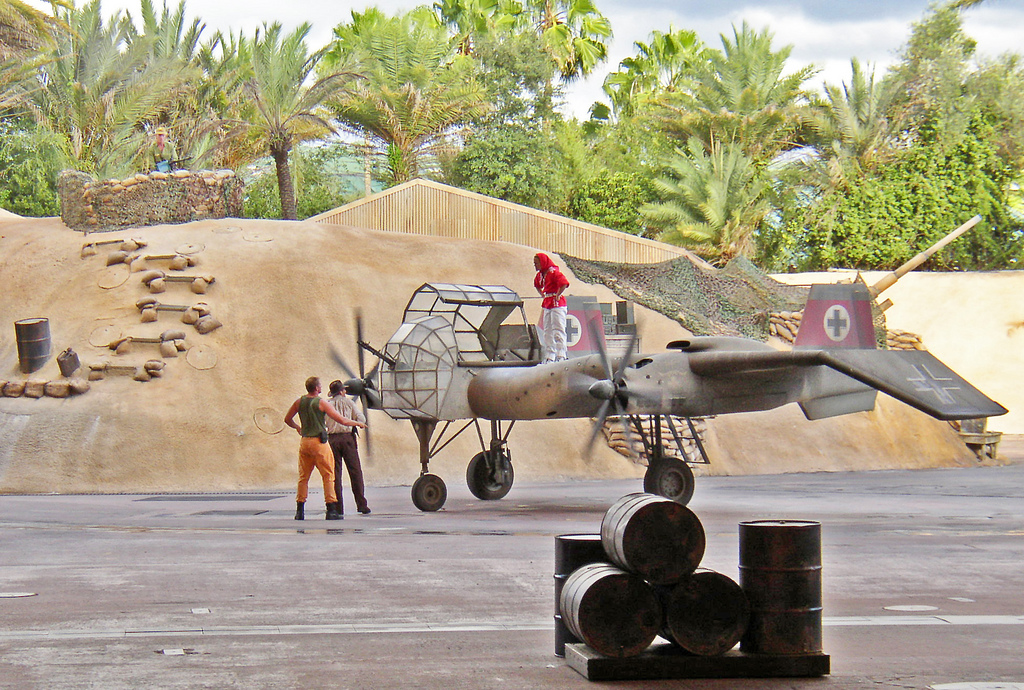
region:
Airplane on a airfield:
[337, 274, 1002, 509]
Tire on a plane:
[412, 474, 447, 512]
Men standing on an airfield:
[282, 376, 371, 523]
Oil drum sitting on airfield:
[737, 512, 827, 652]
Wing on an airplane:
[691, 344, 1005, 424]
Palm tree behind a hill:
[200, 22, 349, 222]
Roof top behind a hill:
[296, 177, 718, 272]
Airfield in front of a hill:
[2, 468, 1021, 681]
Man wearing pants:
[289, 430, 351, 510]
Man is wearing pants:
[289, 425, 348, 508]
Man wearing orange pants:
[285, 422, 358, 509]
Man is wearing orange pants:
[285, 422, 342, 502]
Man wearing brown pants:
[323, 422, 375, 512]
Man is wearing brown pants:
[323, 427, 375, 510]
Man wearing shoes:
[286, 488, 345, 524]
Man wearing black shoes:
[285, 488, 350, 527]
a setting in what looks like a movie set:
[3, 1, 1019, 688]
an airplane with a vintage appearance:
[318, 280, 1008, 514]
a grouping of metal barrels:
[552, 491, 837, 656]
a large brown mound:
[0, 201, 977, 493]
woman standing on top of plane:
[316, 251, 1007, 512]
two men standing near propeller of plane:
[284, 282, 1009, 523]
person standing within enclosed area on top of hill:
[0, 125, 987, 493]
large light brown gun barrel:
[764, 213, 984, 351]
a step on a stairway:
[0, 375, 87, 408]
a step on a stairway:
[97, 320, 187, 350]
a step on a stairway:
[137, 293, 207, 316]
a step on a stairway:
[150, 274, 202, 293]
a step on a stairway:
[131, 253, 185, 263]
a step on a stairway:
[65, 228, 126, 247]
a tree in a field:
[207, 7, 347, 200]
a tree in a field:
[187, 33, 350, 204]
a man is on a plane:
[325, 229, 1017, 531]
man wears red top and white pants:
[521, 242, 579, 374]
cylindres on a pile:
[521, 474, 846, 686]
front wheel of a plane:
[405, 424, 459, 517]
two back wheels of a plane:
[458, 418, 701, 509]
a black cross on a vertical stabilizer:
[778, 264, 887, 353]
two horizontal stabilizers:
[653, 318, 1011, 429]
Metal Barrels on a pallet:
[548, 485, 828, 664]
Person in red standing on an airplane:
[525, 248, 576, 366]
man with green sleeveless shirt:
[281, 370, 371, 525]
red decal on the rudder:
[787, 291, 883, 350]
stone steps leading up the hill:
[0, 216, 217, 413]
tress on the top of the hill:
[0, 1, 1019, 267]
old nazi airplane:
[348, 276, 1012, 515]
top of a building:
[281, 172, 735, 277]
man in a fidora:
[311, 374, 375, 521]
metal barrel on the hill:
[11, 314, 50, 376]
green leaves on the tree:
[889, 107, 965, 197]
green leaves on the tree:
[860, 176, 960, 293]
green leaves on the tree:
[677, 167, 782, 232]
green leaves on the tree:
[640, 28, 691, 93]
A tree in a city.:
[325, 32, 474, 207]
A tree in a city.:
[209, 27, 321, 240]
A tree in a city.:
[604, 153, 737, 265]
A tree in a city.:
[680, 36, 788, 169]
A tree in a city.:
[743, 68, 1010, 338]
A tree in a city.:
[884, 2, 996, 126]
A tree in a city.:
[553, 118, 662, 249]